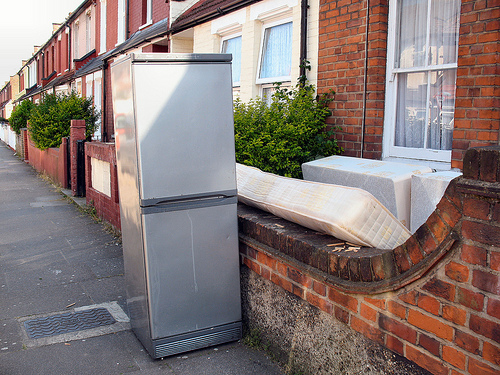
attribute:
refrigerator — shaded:
[73, 38, 254, 358]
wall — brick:
[274, 255, 385, 331]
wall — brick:
[297, 253, 453, 354]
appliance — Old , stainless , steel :
[104, 46, 247, 317]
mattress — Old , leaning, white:
[235, 158, 410, 259]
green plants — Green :
[234, 58, 332, 178]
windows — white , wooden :
[378, 1, 450, 156]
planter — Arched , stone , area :
[27, 94, 87, 157]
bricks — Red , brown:
[462, 71, 493, 103]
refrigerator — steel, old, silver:
[101, 50, 259, 349]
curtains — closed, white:
[400, 6, 452, 66]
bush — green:
[6, 98, 35, 127]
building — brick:
[315, 1, 498, 161]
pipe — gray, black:
[357, 1, 371, 157]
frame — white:
[381, 0, 402, 143]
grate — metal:
[90, 153, 116, 192]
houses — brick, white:
[5, 2, 499, 137]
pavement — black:
[1, 141, 127, 309]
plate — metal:
[83, 155, 118, 197]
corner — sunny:
[124, 52, 191, 109]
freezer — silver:
[102, 52, 258, 340]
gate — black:
[71, 133, 90, 194]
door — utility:
[132, 59, 243, 192]